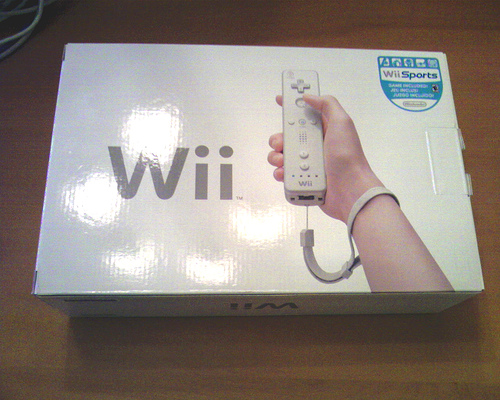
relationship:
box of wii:
[29, 40, 485, 318] [106, 143, 235, 203]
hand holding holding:
[266, 94, 382, 222] [267, 94, 381, 221]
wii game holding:
[106, 143, 235, 203] [267, 94, 381, 221]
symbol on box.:
[106, 145, 234, 201] [29, 40, 485, 318]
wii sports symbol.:
[382, 70, 439, 83] [381, 68, 438, 80]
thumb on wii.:
[299, 93, 355, 137] [280, 68, 329, 206]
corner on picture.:
[0, 0, 54, 59] [0, 0, 497, 400]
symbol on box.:
[228, 299, 301, 313] [29, 40, 485, 318]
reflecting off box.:
[71, 107, 179, 222] [29, 40, 485, 318]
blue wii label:
[376, 54, 444, 111] [375, 54, 444, 114]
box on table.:
[29, 40, 485, 318] [1, 0, 499, 400]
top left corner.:
[0, 1, 57, 62] [0, 0, 54, 59]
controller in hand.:
[280, 67, 328, 206] [266, 94, 382, 222]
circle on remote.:
[294, 96, 309, 109] [280, 68, 329, 206]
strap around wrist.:
[301, 183, 403, 282] [327, 169, 401, 238]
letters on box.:
[106, 145, 235, 201] [29, 40, 485, 318]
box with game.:
[29, 40, 485, 318] [107, 144, 234, 202]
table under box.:
[1, 0, 499, 400] [29, 40, 485, 318]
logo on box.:
[106, 144, 236, 201] [29, 40, 485, 318]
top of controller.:
[281, 69, 324, 129] [281, 67, 326, 207]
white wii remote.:
[281, 69, 328, 207] [280, 68, 329, 206]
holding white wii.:
[267, 94, 381, 221] [280, 68, 329, 206]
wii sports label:
[382, 70, 439, 83] [375, 54, 444, 114]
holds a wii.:
[267, 94, 381, 221] [280, 68, 329, 206]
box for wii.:
[29, 40, 485, 318] [280, 68, 329, 206]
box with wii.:
[29, 40, 485, 318] [280, 68, 329, 206]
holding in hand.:
[267, 94, 381, 221] [266, 94, 382, 222]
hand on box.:
[266, 94, 382, 222] [29, 40, 485, 318]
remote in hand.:
[280, 68, 329, 206] [266, 94, 382, 222]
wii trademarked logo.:
[106, 143, 235, 203] [106, 144, 236, 201]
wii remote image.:
[106, 143, 235, 203] [268, 68, 365, 224]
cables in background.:
[1, 0, 60, 61] [0, 0, 56, 62]